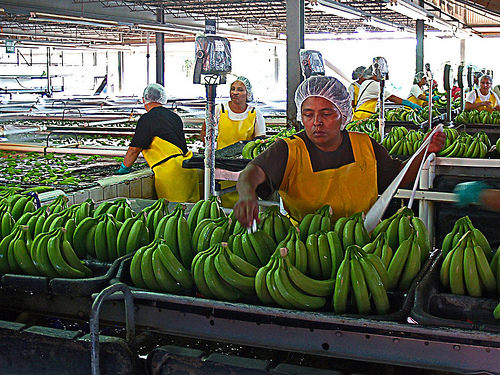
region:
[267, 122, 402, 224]
man wearing a vest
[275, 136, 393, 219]
the vest is yellow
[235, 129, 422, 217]
man's undershirt is black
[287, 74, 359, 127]
man wearing a hair net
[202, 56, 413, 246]
man is touching the bananas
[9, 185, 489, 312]
the bananas are green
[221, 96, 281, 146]
person's undershirt is white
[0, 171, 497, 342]
bananas on a cart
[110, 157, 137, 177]
man's glove is blue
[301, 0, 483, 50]
lights hanging from the cieling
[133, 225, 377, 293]
the bananas are green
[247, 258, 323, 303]
bananas are green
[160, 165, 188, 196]
a yellow apron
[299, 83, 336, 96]
a hair net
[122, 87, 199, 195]
the person is standing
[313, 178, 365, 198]
the apron is yellow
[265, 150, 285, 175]
the shirt the women is wearing is black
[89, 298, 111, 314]
a metal pole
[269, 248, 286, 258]
the stem of the bananas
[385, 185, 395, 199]
white paper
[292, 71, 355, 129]
Man wearing a hair net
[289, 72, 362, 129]
Man is wearing a hair net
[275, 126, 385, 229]
Man wearing an apron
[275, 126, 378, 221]
Man is wearing an apron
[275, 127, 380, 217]
Man wearing a yellow apron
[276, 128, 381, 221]
Man is wearing a yellow apron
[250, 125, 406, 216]
Man wearing a shirt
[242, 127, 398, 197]
Man is wearing a shirt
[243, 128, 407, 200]
Man wearing a brown shirt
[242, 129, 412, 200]
Man is wearing a brown shirt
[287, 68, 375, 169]
the head of a woman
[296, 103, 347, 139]
the nose of a woman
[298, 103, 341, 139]
the eyes of a woman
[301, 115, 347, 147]
the mouth of a woman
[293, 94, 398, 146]
the cheek of a woman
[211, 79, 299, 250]
the arm of a woman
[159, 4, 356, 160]
people in the background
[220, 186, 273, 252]
the hand of a woman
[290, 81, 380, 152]
a woman wearing a plastic bag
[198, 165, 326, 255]
a woman near a lot of bananas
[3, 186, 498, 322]
the bananas on the stand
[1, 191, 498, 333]
the bundles of green bananas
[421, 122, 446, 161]
the bag in the womens hand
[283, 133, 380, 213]
the yellow apron on the women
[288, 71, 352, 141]
the ent on the womens head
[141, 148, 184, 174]
the black strap around the women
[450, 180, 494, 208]
the green glove on the hand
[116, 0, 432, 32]
the rafters on the ceiling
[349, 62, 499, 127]
the people working with the fruit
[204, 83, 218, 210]
the pole by the banana stand